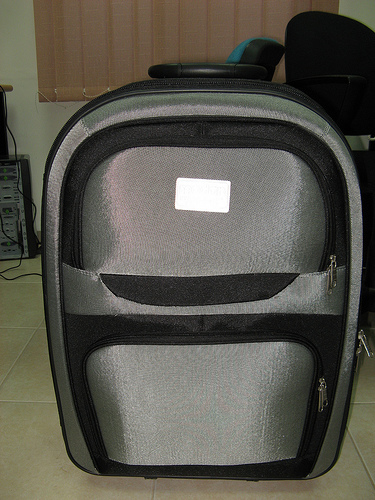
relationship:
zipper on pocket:
[308, 235, 342, 296] [64, 119, 346, 289]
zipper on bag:
[355, 324, 374, 358] [41, 63, 366, 485]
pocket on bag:
[59, 113, 352, 316] [39, 61, 372, 481]